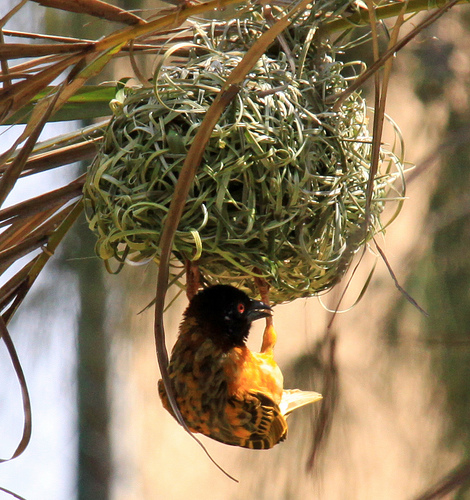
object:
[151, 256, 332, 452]
bird has a head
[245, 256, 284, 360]
bird has legs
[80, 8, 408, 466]
bird has a nest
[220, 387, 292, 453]
bird has a wing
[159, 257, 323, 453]
bird has a tail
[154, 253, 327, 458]
bird has a beak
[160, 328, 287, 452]
body is yellow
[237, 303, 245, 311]
eye is red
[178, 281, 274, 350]
head is fuzzy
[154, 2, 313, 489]
leaf is brown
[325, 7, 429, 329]
leaf is brown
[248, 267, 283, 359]
leg is yellow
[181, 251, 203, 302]
leg is yellow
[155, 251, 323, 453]
bird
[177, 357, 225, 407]
feathers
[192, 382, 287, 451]
wing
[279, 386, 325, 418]
tail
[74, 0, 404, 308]
ball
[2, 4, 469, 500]
tree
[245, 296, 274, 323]
beak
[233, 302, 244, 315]
eye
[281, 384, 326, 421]
tailfeather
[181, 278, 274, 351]
head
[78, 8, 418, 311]
nest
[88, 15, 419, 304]
grass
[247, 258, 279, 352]
leg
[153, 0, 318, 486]
leaf